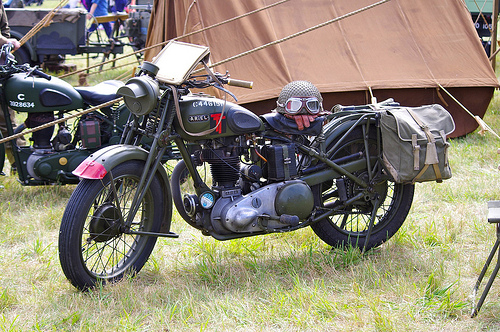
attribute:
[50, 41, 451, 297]
cycle — black, in foreground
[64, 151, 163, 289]
wheel — black, red, green, covered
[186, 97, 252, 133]
gas tank — numbered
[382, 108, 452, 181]
pack — grey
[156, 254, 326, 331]
grass — green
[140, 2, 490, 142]
tent — brown, in back, pitched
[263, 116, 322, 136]
seat — black, leather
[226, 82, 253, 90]
handle — brown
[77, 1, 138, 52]
people — in background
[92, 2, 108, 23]
shirt — blue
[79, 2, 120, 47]
person — walking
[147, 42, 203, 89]
windshield — small